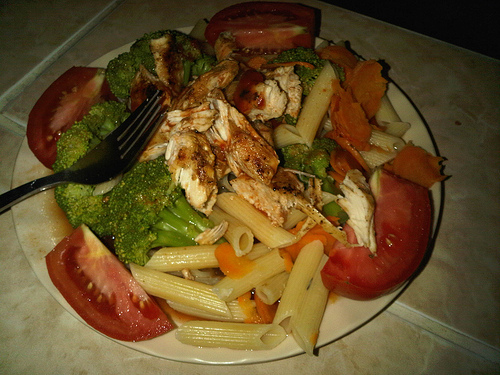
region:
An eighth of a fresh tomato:
[43, 223, 176, 353]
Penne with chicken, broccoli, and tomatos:
[5, 13, 461, 361]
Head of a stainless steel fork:
[63, 89, 165, 194]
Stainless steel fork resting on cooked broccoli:
[2, 86, 170, 222]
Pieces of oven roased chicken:
[164, 77, 274, 198]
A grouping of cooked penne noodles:
[158, 235, 328, 346]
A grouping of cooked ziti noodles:
[157, 247, 325, 338]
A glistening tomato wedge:
[43, 220, 173, 353]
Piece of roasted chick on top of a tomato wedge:
[318, 163, 431, 293]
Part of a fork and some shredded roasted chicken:
[148, 81, 238, 170]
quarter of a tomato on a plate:
[26, 61, 116, 173]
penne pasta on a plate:
[133, 191, 328, 356]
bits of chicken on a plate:
[134, 36, 379, 256]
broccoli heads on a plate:
[53, 31, 228, 268]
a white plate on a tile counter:
[12, 27, 444, 362]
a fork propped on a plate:
[0, 86, 166, 219]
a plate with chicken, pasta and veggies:
[11, 23, 441, 361]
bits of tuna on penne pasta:
[247, 44, 442, 184]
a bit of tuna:
[331, 82, 371, 152]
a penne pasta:
[127, 263, 233, 316]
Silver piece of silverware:
[1, 77, 173, 218]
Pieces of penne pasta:
[101, 184, 352, 363]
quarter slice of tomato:
[39, 219, 196, 358]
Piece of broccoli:
[102, 146, 217, 282]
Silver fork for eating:
[2, 83, 181, 248]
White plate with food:
[8, 16, 450, 365]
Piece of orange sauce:
[198, 234, 269, 289]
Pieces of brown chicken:
[149, 91, 309, 241]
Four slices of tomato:
[26, 3, 443, 343]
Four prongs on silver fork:
[1, 78, 178, 244]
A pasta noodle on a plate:
[177, 313, 289, 353]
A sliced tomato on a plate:
[36, 220, 176, 345]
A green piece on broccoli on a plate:
[101, 161, 225, 266]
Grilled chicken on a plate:
[170, 120, 244, 208]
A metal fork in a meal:
[1, 85, 168, 220]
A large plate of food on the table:
[10, 10, 447, 367]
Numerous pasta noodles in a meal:
[124, 190, 354, 361]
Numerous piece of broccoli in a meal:
[60, 27, 225, 263]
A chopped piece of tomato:
[313, 153, 442, 310]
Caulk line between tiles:
[371, 291, 498, 370]